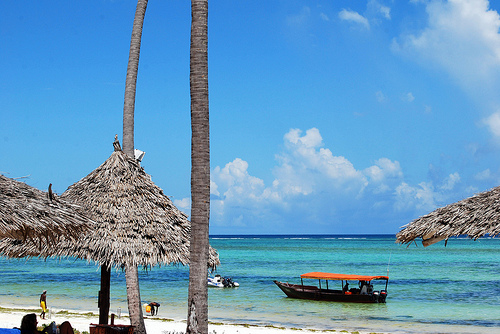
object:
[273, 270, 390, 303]
boat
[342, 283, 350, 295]
people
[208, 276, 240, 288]
raft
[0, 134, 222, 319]
canopy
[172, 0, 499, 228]
clouds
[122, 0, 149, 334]
trunk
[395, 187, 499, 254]
straw canopy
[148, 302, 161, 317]
person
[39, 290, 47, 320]
man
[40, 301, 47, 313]
pants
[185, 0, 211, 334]
trunk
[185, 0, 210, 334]
tree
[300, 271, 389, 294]
canopy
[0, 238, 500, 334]
water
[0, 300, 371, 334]
beach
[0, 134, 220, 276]
roof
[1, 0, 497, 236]
blue sky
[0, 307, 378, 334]
seaweed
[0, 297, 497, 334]
shore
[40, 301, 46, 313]
swim trunks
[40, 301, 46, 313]
shorts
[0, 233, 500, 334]
ocean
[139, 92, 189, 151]
blue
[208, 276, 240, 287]
boat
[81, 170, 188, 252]
leaves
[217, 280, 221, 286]
engine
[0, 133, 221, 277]
umbrella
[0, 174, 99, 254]
umbrella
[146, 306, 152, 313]
bucket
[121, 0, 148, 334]
tree